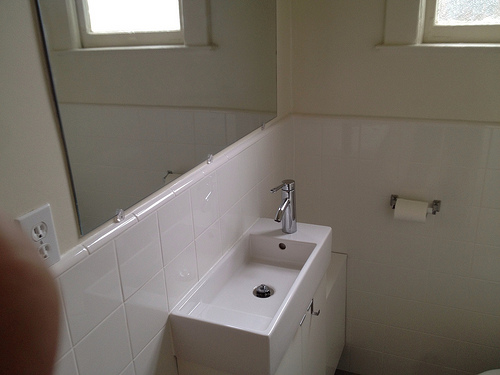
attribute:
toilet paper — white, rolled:
[393, 197, 429, 223]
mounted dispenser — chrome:
[389, 194, 441, 216]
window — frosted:
[433, 1, 500, 26]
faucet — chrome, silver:
[269, 179, 298, 234]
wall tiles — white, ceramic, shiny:
[33, 116, 499, 374]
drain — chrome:
[252, 284, 275, 297]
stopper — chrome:
[255, 283, 269, 294]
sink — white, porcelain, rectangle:
[177, 216, 332, 371]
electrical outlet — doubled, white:
[15, 205, 60, 269]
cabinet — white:
[270, 276, 338, 374]